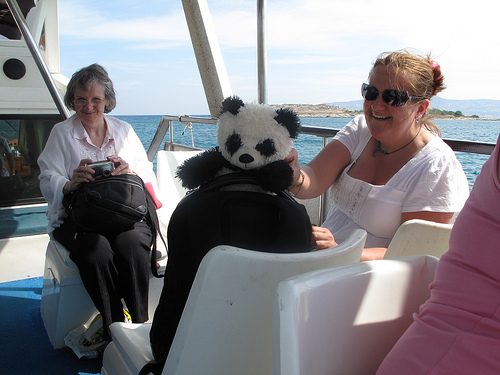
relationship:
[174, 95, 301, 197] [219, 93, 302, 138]
panda has black ears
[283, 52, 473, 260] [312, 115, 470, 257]
woman wearing a white top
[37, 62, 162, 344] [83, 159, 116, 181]
woman holding camera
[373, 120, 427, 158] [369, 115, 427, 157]
necklace hanging from neck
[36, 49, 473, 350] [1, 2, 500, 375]
two women are inside a boat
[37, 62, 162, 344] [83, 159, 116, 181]
woman has a camera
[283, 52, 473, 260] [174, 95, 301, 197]
woman holding panda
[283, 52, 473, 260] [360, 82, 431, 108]
woman has sunglasses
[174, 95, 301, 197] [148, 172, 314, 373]
panda on top of luggage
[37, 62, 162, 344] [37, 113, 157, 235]
woman has white shirt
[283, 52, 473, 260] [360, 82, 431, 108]
woman wearing sunglasses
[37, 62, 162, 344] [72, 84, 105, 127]
woman has a face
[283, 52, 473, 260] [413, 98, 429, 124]
woman has ear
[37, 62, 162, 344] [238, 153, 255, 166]
woman has a nose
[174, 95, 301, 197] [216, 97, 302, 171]
stuffed animal has a head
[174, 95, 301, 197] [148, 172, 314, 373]
stuffed animal on top of luggage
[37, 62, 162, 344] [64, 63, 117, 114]
woman has gray hair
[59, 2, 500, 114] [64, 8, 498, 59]
sky has clouds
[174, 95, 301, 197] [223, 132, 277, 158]
stuffed animal has black eye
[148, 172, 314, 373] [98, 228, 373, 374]
bag on top of chair